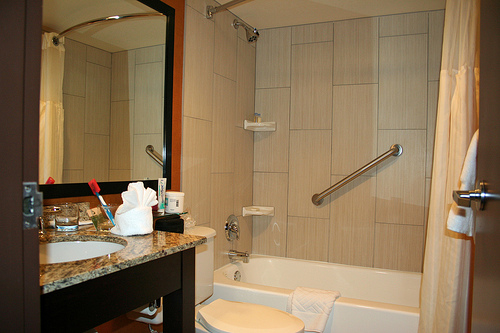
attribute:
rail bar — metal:
[310, 142, 404, 207]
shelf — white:
[241, 118, 276, 133]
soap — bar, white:
[250, 206, 260, 212]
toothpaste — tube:
[155, 174, 167, 215]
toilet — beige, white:
[126, 223, 305, 332]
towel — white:
[289, 284, 340, 332]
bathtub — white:
[198, 250, 421, 332]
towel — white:
[445, 125, 478, 237]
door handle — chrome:
[449, 177, 486, 209]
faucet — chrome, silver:
[229, 244, 252, 264]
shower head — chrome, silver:
[231, 17, 258, 43]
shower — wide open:
[179, 0, 445, 333]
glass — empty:
[96, 200, 120, 229]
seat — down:
[199, 294, 304, 332]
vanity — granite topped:
[38, 212, 208, 332]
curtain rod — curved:
[53, 9, 164, 44]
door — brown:
[465, 0, 498, 332]